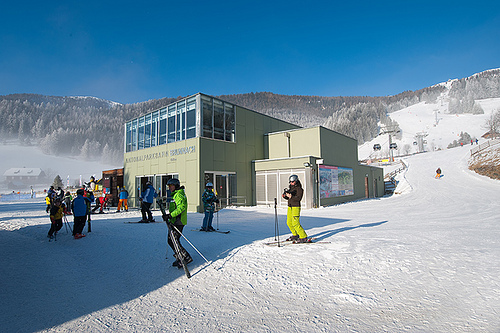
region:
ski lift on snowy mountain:
[364, 110, 444, 157]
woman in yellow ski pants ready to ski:
[268, 167, 328, 260]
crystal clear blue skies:
[58, 48, 398, 78]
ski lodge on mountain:
[98, 100, 252, 179]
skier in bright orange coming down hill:
[424, 157, 471, 204]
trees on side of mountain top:
[15, 87, 109, 164]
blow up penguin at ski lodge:
[84, 171, 106, 192]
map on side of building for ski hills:
[313, 161, 378, 201]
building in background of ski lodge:
[4, 162, 54, 187]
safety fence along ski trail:
[463, 132, 498, 194]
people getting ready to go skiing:
[47, 141, 324, 290]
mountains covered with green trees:
[18, 78, 109, 170]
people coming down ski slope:
[383, 107, 495, 242]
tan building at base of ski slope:
[106, 92, 394, 229]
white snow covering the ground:
[342, 248, 454, 313]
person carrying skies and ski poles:
[147, 167, 213, 282]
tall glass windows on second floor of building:
[118, 87, 244, 161]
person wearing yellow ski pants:
[258, 162, 328, 260]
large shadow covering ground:
[72, 238, 152, 324]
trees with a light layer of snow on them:
[38, 102, 84, 149]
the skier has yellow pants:
[253, 147, 344, 254]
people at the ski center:
[72, 30, 469, 317]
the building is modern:
[93, 24, 405, 294]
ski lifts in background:
[350, 82, 473, 227]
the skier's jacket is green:
[138, 163, 263, 309]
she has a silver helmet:
[261, 141, 354, 253]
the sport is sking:
[25, 45, 460, 292]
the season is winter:
[23, 31, 437, 301]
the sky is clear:
[171, 25, 277, 77]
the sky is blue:
[188, 19, 315, 77]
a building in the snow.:
[123, 90, 385, 212]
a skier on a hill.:
[433, 167, 445, 180]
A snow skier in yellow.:
[264, 173, 331, 246]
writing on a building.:
[122, 144, 196, 164]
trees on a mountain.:
[0, 67, 498, 165]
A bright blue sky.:
[3, 3, 495, 106]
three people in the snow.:
[161, 172, 308, 270]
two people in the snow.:
[199, 173, 308, 245]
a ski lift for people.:
[373, 121, 403, 158]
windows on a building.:
[124, 94, 236, 154]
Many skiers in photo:
[24, 154, 345, 263]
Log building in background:
[3, 165, 55, 190]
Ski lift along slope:
[355, 106, 442, 161]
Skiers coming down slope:
[429, 135, 485, 188]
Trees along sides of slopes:
[372, 63, 499, 159]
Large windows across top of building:
[112, 92, 240, 154]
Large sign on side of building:
[316, 159, 362, 203]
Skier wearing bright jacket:
[156, 177, 211, 237]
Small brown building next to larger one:
[87, 165, 135, 214]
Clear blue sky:
[1, 0, 498, 70]